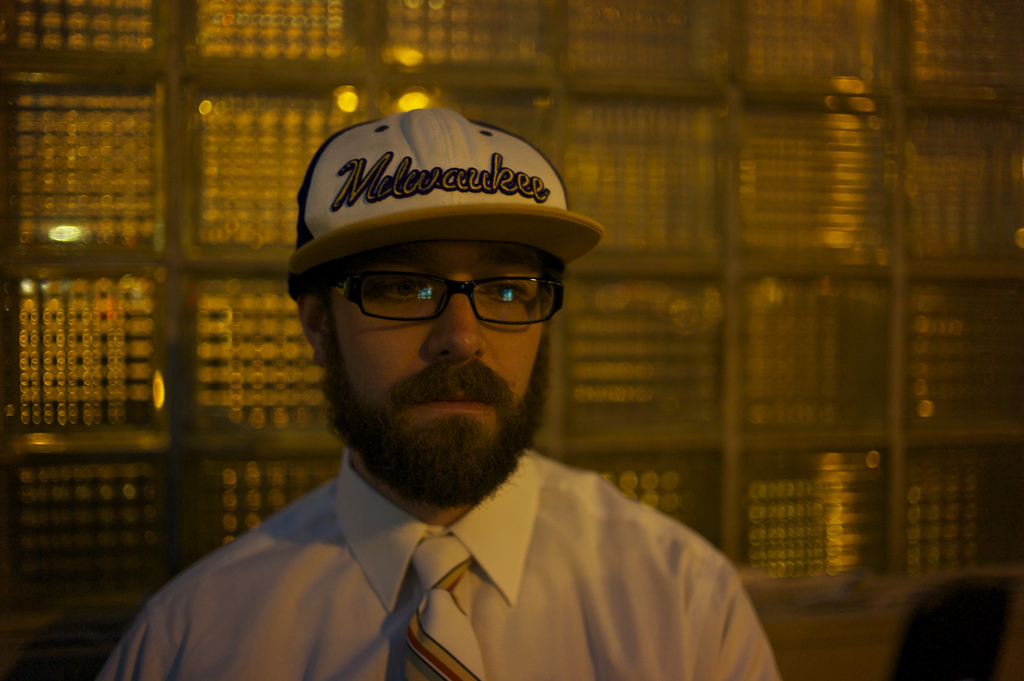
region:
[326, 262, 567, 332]
Dark framed eyeglasses.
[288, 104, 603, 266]
White, black and yellow cap.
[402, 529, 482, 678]
A striped man's tie.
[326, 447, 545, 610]
Collar of a white shirt.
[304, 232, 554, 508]
Face of a bearded man.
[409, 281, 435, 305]
Blue reflection on glass.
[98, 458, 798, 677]
Clean white shirt.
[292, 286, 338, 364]
Right ear of a person.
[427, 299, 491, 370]
Nose of a person.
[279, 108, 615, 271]
white black and yellow hat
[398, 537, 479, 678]
striped tie man is wearing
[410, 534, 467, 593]
knot on the necktie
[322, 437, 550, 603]
collar of the white shirt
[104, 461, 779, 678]
white shirt the man is wearing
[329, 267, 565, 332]
eyeglasses with black frames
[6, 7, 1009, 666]
glass wall behind the man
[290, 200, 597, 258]
yellow brim of the hat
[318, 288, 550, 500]
beard on the man's face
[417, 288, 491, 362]
nose on the man's face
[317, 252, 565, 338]
a person wearing eyeglasses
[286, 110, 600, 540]
a man wearing a ball cap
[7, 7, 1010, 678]
a man in front of a glass block wall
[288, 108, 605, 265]
a hat with a yellow bill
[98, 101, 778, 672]
a man wearing a neck tie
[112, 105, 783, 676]
a man wearing a white dress shirt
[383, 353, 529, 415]
a brown haired mustache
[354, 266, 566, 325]
reflections in the lenses of eyeglasses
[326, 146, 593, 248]
a sports team embroidered on a hat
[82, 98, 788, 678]
The man is wearing a cap.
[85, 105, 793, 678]
The man is wearing glasses.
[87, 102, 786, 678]
The man is wearing a tie.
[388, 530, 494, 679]
The tie has stripes.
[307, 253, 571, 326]
The frames on the glasses are dark.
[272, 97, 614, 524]
The man's moustache is neatly trimmed.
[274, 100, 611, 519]
The man's beard is neatly trimmed.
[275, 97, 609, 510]
The man's bottom lip is visible.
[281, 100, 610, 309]
The lettering on the cap is embroidered.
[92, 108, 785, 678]
The man's shirt has a collar.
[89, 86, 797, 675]
Man wearing white hat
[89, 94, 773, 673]
Man in baseball cap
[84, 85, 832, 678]
Man is wearing glasses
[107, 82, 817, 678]
Man with a trimmed beard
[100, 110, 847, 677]
Man in white shirt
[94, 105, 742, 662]
Man wearing tie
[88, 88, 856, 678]
Man wearing black glasses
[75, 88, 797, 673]
Man wearing striped tie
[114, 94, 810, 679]
Man wearing a cap with a logo on it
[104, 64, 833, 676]
Man looking at something in distance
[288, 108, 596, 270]
white and yellow baseball cap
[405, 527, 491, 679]
white and yellow neck tie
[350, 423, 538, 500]
dark brown beard on chin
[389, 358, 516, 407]
dark brown mustache on face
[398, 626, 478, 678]
colorful stripe on neck tie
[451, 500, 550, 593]
white collar on dress shirt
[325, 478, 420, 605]
white collar on dress shirt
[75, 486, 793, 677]
white long sleeve dress shirt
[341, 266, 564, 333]
black framed glasses on face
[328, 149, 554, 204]
yellow and black letters on baseball cap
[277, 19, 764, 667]
a man wearing a hat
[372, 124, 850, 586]
a man wearing a baseball cap